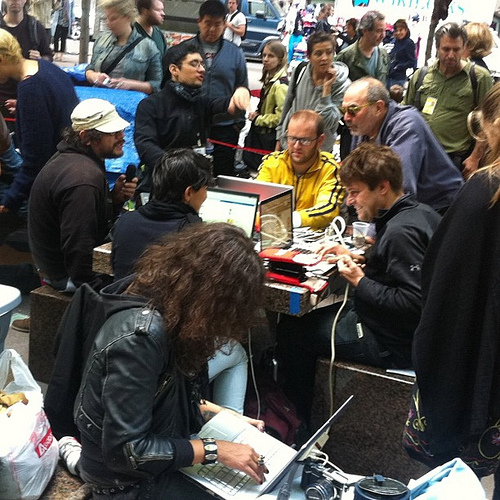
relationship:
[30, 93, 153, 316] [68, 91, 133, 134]
man wearing hat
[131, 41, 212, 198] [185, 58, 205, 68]
man wearing eye glasses